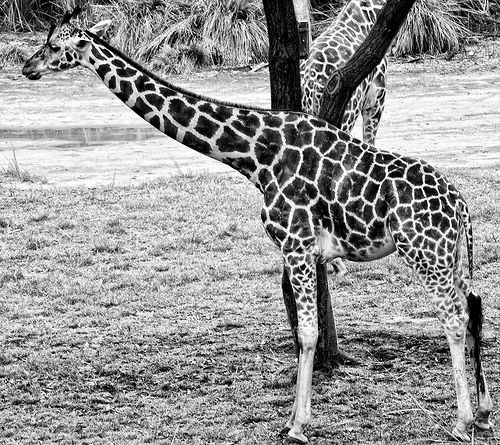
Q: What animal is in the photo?
A: Giraffes.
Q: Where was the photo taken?
A: In a zoo.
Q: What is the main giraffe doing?
A: Standing.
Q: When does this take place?
A: Daytime.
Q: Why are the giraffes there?
A: To entertain tourists.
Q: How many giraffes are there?
A: Two.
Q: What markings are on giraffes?
A: Large irregular shapes.